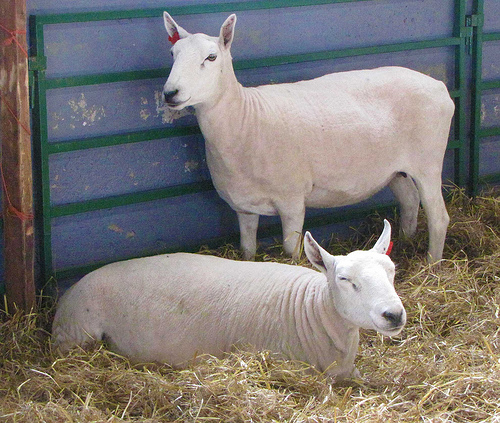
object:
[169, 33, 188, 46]
tag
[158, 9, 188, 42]
ear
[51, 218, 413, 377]
sheep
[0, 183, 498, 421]
hay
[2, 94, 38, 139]
thread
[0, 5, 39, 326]
bar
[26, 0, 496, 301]
railings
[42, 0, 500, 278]
wall